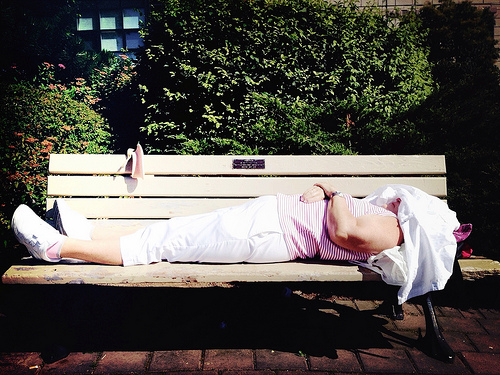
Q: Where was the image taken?
A: It was taken at the sidewalk.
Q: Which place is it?
A: It is a sidewalk.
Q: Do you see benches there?
A: Yes, there is a bench.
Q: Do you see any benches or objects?
A: Yes, there is a bench.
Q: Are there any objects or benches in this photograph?
A: Yes, there is a bench.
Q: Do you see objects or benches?
A: Yes, there is a bench.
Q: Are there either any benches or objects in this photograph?
A: Yes, there is a bench.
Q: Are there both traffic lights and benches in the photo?
A: No, there is a bench but no traffic lights.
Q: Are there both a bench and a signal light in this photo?
A: No, there is a bench but no traffic lights.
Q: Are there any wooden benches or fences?
A: Yes, there is a wood bench.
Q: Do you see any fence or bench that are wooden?
A: Yes, the bench is wooden.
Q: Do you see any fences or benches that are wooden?
A: Yes, the bench is wooden.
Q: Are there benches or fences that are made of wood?
A: Yes, the bench is made of wood.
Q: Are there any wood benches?
A: Yes, there is a bench that is made of wood.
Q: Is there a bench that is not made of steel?
A: Yes, there is a bench that is made of wood.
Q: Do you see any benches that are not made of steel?
A: Yes, there is a bench that is made of wood.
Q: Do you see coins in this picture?
A: No, there are no coins.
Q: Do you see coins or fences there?
A: No, there are no coins or fences.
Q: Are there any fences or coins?
A: No, there are no coins or fences.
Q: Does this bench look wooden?
A: Yes, the bench is wooden.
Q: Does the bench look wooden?
A: Yes, the bench is wooden.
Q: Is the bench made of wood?
A: Yes, the bench is made of wood.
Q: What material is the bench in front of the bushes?
A: The bench is made of wood.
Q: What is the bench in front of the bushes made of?
A: The bench is made of wood.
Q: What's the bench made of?
A: The bench is made of wood.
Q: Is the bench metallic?
A: No, the bench is wooden.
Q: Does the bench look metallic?
A: No, the bench is wooden.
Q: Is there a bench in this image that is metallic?
A: No, there is a bench but it is wooden.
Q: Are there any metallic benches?
A: No, there is a bench but it is wooden.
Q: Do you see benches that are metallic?
A: No, there is a bench but it is wooden.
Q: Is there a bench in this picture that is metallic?
A: No, there is a bench but it is wooden.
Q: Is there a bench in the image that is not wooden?
A: No, there is a bench but it is wooden.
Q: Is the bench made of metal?
A: No, the bench is made of wood.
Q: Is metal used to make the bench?
A: No, the bench is made of wood.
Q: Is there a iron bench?
A: No, there is a bench but it is made of wood.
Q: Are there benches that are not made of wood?
A: No, there is a bench but it is made of wood.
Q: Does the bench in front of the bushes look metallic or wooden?
A: The bench is wooden.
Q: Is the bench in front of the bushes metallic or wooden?
A: The bench is wooden.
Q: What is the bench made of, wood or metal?
A: The bench is made of wood.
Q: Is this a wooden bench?
A: Yes, this is a wooden bench.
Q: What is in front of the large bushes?
A: The bench is in front of the bushes.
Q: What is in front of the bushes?
A: The bench is in front of the bushes.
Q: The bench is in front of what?
A: The bench is in front of the bushes.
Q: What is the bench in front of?
A: The bench is in front of the bushes.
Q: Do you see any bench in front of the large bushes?
A: Yes, there is a bench in front of the bushes.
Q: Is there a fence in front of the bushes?
A: No, there is a bench in front of the bushes.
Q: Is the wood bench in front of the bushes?
A: Yes, the bench is in front of the bushes.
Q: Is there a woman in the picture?
A: Yes, there is a woman.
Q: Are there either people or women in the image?
A: Yes, there is a woman.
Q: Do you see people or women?
A: Yes, there is a woman.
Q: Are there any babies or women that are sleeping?
A: Yes, the woman is sleeping.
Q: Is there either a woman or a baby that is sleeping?
A: Yes, the woman is sleeping.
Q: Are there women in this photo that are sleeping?
A: Yes, there is a woman that is sleeping.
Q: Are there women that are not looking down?
A: Yes, there is a woman that is sleeping.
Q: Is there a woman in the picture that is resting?
A: Yes, there is a woman that is resting.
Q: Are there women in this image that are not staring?
A: Yes, there is a woman that is resting.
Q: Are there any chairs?
A: No, there are no chairs.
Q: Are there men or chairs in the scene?
A: No, there are no chairs or men.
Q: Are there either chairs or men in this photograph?
A: No, there are no chairs or men.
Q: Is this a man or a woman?
A: This is a woman.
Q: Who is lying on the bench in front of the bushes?
A: The woman is lying on the bench.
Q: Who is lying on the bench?
A: The woman is lying on the bench.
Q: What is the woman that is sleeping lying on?
A: The woman is lying on the bench.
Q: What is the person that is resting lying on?
A: The woman is lying on the bench.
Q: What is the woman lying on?
A: The woman is lying on the bench.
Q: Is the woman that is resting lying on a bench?
A: Yes, the woman is lying on a bench.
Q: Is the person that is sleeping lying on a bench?
A: Yes, the woman is lying on a bench.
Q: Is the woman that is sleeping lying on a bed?
A: No, the woman is lying on a bench.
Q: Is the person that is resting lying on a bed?
A: No, the woman is lying on a bench.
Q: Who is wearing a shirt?
A: The woman is wearing a shirt.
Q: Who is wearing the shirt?
A: The woman is wearing a shirt.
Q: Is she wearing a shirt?
A: Yes, the woman is wearing a shirt.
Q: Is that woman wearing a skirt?
A: No, the woman is wearing a shirt.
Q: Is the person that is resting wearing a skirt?
A: No, the woman is wearing a shirt.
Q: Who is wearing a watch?
A: The woman is wearing a watch.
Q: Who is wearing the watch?
A: The woman is wearing a watch.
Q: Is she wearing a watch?
A: Yes, the woman is wearing a watch.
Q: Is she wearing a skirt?
A: No, the woman is wearing a watch.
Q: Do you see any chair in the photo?
A: No, there are no chairs.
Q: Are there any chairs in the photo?
A: No, there are no chairs.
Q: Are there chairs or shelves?
A: No, there are no chairs or shelves.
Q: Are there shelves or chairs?
A: No, there are no chairs or shelves.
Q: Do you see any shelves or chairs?
A: No, there are no chairs or shelves.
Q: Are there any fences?
A: No, there are no fences.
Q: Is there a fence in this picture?
A: No, there are no fences.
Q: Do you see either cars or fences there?
A: No, there are no fences or cars.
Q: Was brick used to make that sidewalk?
A: Yes, the sidewalk is made of brick.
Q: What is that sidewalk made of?
A: The sidewalk is made of brick.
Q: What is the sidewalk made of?
A: The sidewalk is made of brick.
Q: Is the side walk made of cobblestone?
A: No, the side walk is made of brick.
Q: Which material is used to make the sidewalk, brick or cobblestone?
A: The sidewalk is made of brick.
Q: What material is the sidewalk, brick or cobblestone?
A: The sidewalk is made of brick.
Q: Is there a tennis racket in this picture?
A: No, there are no rackets.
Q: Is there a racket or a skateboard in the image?
A: No, there are no rackets or skateboards.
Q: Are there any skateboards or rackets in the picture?
A: No, there are no rackets or skateboards.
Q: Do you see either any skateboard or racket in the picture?
A: No, there are no rackets or skateboards.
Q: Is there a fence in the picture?
A: No, there are no fences.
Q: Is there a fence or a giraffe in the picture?
A: No, there are no fences or giraffes.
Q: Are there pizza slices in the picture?
A: No, there are no pizza slices.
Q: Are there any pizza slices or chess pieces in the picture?
A: No, there are no pizza slices or chess pieces.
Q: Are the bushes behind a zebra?
A: No, the bushes are behind the bench.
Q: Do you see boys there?
A: No, there are no boys.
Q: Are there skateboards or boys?
A: No, there are no boys or skateboards.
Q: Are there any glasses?
A: No, there are no glasses.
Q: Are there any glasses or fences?
A: No, there are no glasses or fences.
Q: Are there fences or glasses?
A: No, there are no glasses or fences.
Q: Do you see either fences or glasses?
A: No, there are no glasses or fences.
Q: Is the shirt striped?
A: Yes, the shirt is striped.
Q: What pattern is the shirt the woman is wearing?
A: The shirt is striped.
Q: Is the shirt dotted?
A: No, the shirt is striped.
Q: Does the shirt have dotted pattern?
A: No, the shirt is striped.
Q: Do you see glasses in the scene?
A: No, there are no glasses.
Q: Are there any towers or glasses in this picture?
A: No, there are no glasses or towers.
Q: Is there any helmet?
A: No, there are no helmets.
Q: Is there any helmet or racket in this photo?
A: No, there are no helmets or rackets.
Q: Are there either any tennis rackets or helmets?
A: No, there are no helmets or tennis rackets.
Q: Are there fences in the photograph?
A: No, there are no fences.